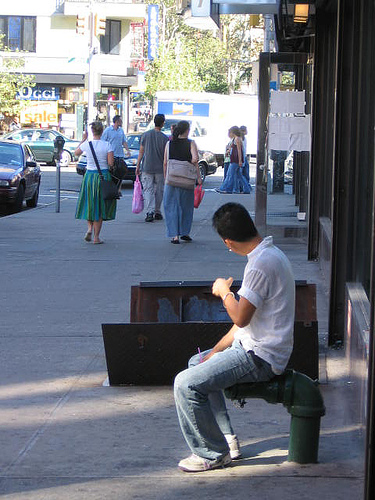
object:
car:
[0, 127, 81, 161]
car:
[121, 123, 143, 173]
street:
[27, 146, 78, 210]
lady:
[72, 117, 127, 246]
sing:
[23, 72, 84, 138]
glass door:
[257, 45, 307, 241]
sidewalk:
[1, 183, 353, 497]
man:
[171, 200, 295, 471]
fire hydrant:
[223, 361, 325, 469]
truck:
[150, 85, 261, 162]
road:
[1, 148, 294, 189]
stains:
[116, 407, 123, 413]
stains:
[247, 434, 253, 438]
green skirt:
[74, 169, 117, 222]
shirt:
[80, 139, 113, 170]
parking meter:
[52, 135, 65, 212]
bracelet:
[222, 290, 234, 308]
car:
[1, 141, 41, 213]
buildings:
[1, 0, 154, 146]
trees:
[197, 9, 261, 95]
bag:
[87, 144, 119, 200]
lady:
[161, 121, 204, 245]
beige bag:
[166, 158, 197, 188]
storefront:
[95, 80, 129, 147]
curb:
[3, 192, 75, 241]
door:
[129, 279, 318, 324]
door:
[98, 321, 321, 388]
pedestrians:
[132, 113, 170, 222]